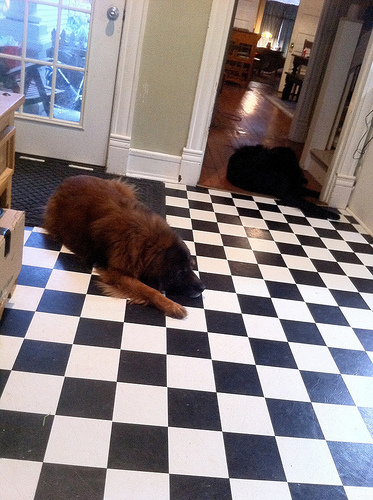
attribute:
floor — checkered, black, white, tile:
[0, 154, 370, 499]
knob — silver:
[107, 4, 122, 22]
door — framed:
[4, 2, 128, 166]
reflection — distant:
[230, 83, 270, 120]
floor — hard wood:
[196, 75, 328, 204]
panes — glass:
[1, 1, 92, 131]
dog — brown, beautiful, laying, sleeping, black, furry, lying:
[43, 167, 208, 321]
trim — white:
[315, 32, 372, 208]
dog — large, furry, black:
[223, 140, 347, 221]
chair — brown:
[225, 46, 248, 91]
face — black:
[164, 257, 214, 298]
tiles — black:
[279, 239, 340, 289]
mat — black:
[7, 152, 165, 243]